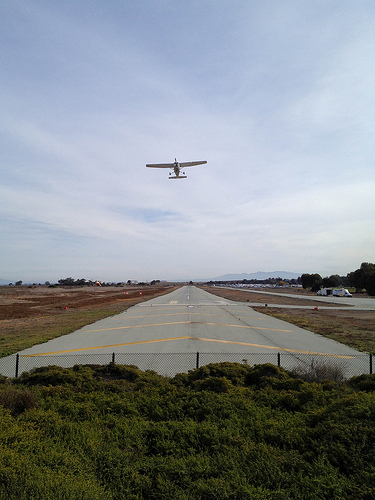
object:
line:
[14, 334, 362, 360]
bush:
[189, 280, 193, 285]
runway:
[1, 286, 374, 379]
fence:
[2, 352, 374, 374]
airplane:
[146, 159, 207, 181]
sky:
[1, 0, 374, 284]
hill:
[206, 271, 300, 281]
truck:
[333, 287, 353, 297]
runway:
[220, 285, 374, 310]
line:
[140, 303, 241, 307]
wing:
[180, 160, 208, 168]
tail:
[169, 176, 187, 179]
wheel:
[182, 172, 185, 175]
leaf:
[2, 375, 15, 394]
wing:
[146, 163, 174, 168]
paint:
[65, 320, 291, 333]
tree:
[299, 363, 345, 382]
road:
[251, 301, 352, 309]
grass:
[339, 316, 373, 346]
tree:
[58, 277, 75, 286]